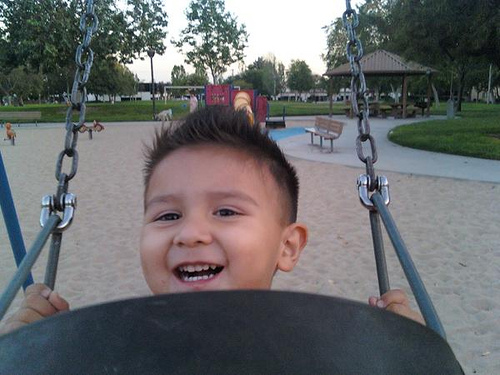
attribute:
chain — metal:
[344, 1, 398, 210]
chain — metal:
[56, 2, 99, 216]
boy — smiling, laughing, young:
[24, 118, 418, 324]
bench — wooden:
[298, 109, 351, 154]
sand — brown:
[328, 187, 480, 281]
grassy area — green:
[393, 118, 497, 167]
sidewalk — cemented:
[278, 120, 500, 195]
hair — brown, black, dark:
[133, 104, 303, 199]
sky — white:
[119, 2, 343, 77]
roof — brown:
[328, 46, 431, 73]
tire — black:
[1, 287, 469, 375]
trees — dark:
[1, 0, 157, 122]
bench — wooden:
[2, 108, 45, 128]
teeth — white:
[175, 262, 220, 283]